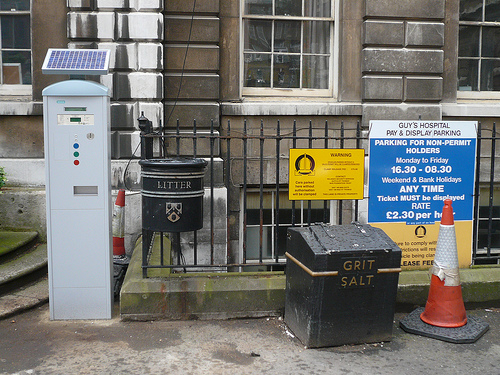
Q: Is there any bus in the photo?
A: No, there are no buses.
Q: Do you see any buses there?
A: No, there are no buses.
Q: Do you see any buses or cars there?
A: No, there are no buses or cars.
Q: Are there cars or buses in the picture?
A: No, there are no buses or cars.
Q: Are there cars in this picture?
A: No, there are no cars.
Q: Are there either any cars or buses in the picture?
A: No, there are no cars or buses.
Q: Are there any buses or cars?
A: No, there are no cars or buses.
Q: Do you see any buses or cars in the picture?
A: No, there are no cars or buses.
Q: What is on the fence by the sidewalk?
A: The sign is on the fence.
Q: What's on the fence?
A: The sign is on the fence.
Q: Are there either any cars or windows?
A: Yes, there is a window.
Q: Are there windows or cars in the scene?
A: Yes, there is a window.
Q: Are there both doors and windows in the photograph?
A: No, there is a window but no doors.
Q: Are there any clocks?
A: No, there are no clocks.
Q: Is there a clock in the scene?
A: No, there are no clocks.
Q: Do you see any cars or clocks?
A: No, there are no clocks or cars.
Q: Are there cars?
A: No, there are no cars.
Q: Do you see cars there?
A: No, there are no cars.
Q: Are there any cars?
A: No, there are no cars.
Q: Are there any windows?
A: Yes, there is a window.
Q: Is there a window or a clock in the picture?
A: Yes, there is a window.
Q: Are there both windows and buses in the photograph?
A: No, there is a window but no buses.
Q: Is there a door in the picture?
A: No, there are no doors.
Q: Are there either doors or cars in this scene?
A: No, there are no doors or cars.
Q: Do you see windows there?
A: Yes, there is a window.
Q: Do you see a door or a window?
A: Yes, there is a window.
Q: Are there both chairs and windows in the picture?
A: No, there is a window but no chairs.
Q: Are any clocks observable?
A: No, there are no clocks.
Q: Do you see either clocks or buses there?
A: No, there are no clocks or buses.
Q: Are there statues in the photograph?
A: No, there are no statues.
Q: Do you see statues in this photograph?
A: No, there are no statues.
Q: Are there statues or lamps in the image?
A: No, there are no statues or lamps.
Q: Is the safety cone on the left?
A: No, the safety cone is on the right of the image.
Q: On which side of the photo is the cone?
A: The cone is on the right of the image.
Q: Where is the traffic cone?
A: The traffic cone is on the sidewalk.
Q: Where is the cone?
A: The traffic cone is on the sidewalk.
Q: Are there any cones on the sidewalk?
A: Yes, there is a cone on the sidewalk.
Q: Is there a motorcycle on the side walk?
A: No, there is a cone on the side walk.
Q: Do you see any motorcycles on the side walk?
A: No, there is a cone on the side walk.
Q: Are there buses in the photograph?
A: No, there are no buses.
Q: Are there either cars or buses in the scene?
A: No, there are no buses or cars.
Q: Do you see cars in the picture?
A: No, there are no cars.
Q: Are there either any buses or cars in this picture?
A: No, there are no cars or buses.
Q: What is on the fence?
A: The sign is on the fence.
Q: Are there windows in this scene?
A: Yes, there is a window.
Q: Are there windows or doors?
A: Yes, there is a window.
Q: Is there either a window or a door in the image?
A: Yes, there is a window.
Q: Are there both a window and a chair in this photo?
A: No, there is a window but no chairs.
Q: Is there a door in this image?
A: No, there are no doors.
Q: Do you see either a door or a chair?
A: No, there are no doors or chairs.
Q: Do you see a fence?
A: Yes, there is a fence.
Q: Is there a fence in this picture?
A: Yes, there is a fence.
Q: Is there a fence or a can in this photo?
A: Yes, there is a fence.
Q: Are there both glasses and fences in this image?
A: No, there is a fence but no glasses.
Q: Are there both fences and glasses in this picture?
A: No, there is a fence but no glasses.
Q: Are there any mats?
A: No, there are no mats.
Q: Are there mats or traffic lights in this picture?
A: No, there are no mats or traffic lights.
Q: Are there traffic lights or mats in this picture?
A: No, there are no mats or traffic lights.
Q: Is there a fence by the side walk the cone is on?
A: Yes, there is a fence by the sidewalk.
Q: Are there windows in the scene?
A: Yes, there is a window.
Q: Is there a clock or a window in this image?
A: Yes, there is a window.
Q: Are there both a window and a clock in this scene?
A: No, there is a window but no clocks.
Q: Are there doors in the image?
A: No, there are no doors.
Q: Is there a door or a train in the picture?
A: No, there are no doors or trains.